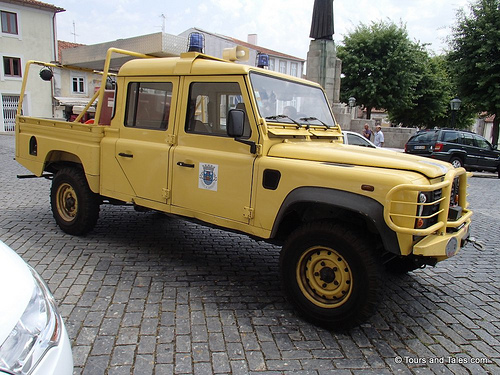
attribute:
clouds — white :
[122, 1, 214, 28]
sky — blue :
[38, 0, 480, 78]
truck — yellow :
[20, 40, 472, 312]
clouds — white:
[389, 9, 451, 43]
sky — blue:
[183, 5, 297, 30]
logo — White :
[198, 162, 223, 191]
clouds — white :
[86, 2, 138, 27]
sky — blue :
[38, 0, 480, 65]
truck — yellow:
[16, 34, 346, 293]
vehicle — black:
[50, 47, 484, 344]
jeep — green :
[403, 127, 498, 174]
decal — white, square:
[198, 162, 216, 191]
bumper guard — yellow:
[384, 166, 472, 254]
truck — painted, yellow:
[14, 30, 486, 333]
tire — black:
[266, 208, 383, 373]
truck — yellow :
[101, 76, 389, 249]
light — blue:
[185, 30, 205, 52]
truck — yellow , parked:
[51, 64, 396, 298]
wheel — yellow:
[273, 223, 383, 335]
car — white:
[1, 235, 91, 373]